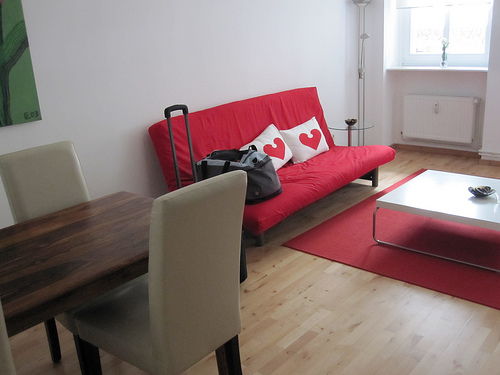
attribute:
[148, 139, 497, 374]
floor — wooden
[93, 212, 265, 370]
chair — tan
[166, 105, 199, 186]
handle on luggage — black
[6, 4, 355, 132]
wall — light blue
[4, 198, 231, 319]
table — wooden, dark brown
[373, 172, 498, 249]
table — silver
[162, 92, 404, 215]
sofa bed — red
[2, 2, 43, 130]
painting — green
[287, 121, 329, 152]
pillow — white, red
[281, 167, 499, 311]
carpet — red